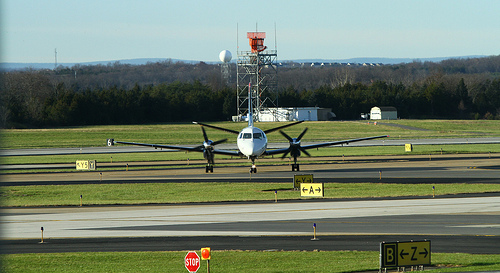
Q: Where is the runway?
A: Under the plane.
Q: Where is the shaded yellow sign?
A: Under the plane.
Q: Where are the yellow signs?
A: On the plane.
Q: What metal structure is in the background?
A: Control post.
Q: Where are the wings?
A: On the plane.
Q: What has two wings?
A: The plane.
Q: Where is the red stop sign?
A: On the field.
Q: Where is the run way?
A: In the field.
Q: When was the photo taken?
A: Daytime.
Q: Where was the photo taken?
A: Airport.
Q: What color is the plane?
A: White.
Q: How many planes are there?
A: One.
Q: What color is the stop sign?
A: Red.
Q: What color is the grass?
A: Green.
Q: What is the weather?
A: Sunny.